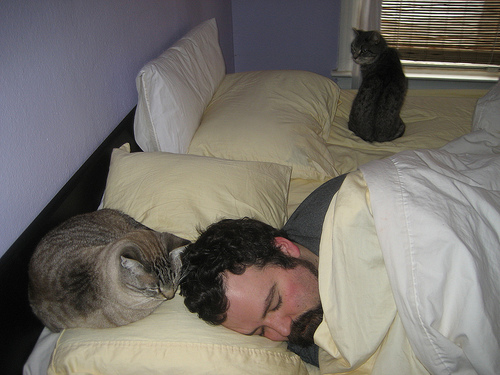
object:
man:
[180, 154, 500, 371]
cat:
[28, 206, 192, 335]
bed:
[0, 60, 498, 375]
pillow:
[186, 65, 343, 176]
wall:
[0, 0, 135, 147]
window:
[372, 1, 500, 72]